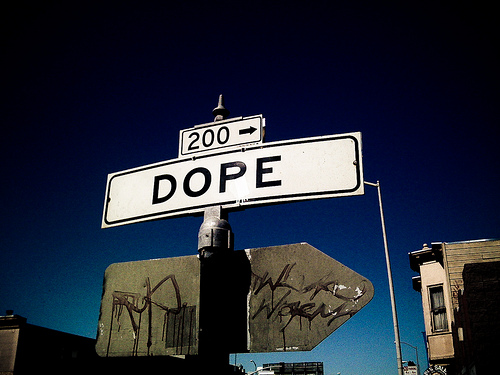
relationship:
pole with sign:
[195, 91, 230, 373] [176, 114, 264, 159]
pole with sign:
[195, 91, 230, 373] [100, 130, 363, 235]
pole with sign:
[195, 91, 230, 373] [90, 241, 375, 358]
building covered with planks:
[407, 237, 499, 372] [442, 239, 498, 314]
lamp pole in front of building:
[377, 185, 409, 373] [407, 237, 499, 372]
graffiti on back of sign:
[251, 259, 344, 329] [74, 107, 346, 227]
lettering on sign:
[184, 126, 254, 148] [82, 95, 394, 228]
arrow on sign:
[232, 118, 260, 140] [76, 100, 391, 247]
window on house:
[417, 286, 481, 337] [383, 237, 481, 331]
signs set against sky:
[156, 97, 336, 197] [5, 0, 496, 374]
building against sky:
[407, 237, 499, 374] [5, 0, 496, 374]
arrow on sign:
[238, 126, 257, 136] [172, 108, 289, 154]